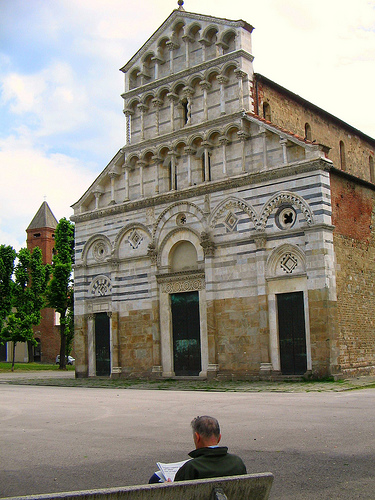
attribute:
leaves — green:
[17, 243, 46, 292]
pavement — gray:
[5, 386, 371, 416]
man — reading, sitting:
[152, 426, 279, 489]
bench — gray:
[94, 480, 292, 499]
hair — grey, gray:
[185, 399, 228, 431]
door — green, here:
[156, 274, 236, 399]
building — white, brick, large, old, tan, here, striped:
[1, 39, 369, 390]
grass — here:
[10, 348, 55, 373]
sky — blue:
[21, 34, 141, 176]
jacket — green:
[178, 448, 255, 477]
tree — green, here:
[37, 220, 82, 383]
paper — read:
[143, 446, 191, 483]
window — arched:
[61, 170, 350, 282]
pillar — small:
[198, 144, 216, 184]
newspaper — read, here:
[140, 459, 194, 485]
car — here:
[56, 351, 78, 369]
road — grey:
[64, 389, 171, 473]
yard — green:
[13, 335, 80, 394]